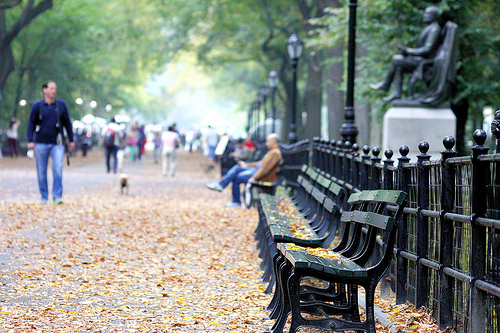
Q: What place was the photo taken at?
A: It was taken at the park.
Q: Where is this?
A: This is at the park.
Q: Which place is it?
A: It is a park.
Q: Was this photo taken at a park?
A: Yes, it was taken in a park.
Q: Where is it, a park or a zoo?
A: It is a park.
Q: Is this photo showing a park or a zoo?
A: It is showing a park.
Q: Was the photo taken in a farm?
A: No, the picture was taken in a park.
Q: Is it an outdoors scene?
A: Yes, it is outdoors.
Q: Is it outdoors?
A: Yes, it is outdoors.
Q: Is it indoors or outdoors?
A: It is outdoors.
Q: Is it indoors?
A: No, it is outdoors.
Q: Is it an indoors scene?
A: No, it is outdoors.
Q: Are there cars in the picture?
A: No, there are no cars.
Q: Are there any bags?
A: No, there are no bags.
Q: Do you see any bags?
A: No, there are no bags.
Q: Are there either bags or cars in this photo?
A: No, there are no bags or cars.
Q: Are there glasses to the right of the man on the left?
A: No, there are people to the right of the man.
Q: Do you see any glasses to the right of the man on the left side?
A: No, there are people to the right of the man.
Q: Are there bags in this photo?
A: No, there are no bags.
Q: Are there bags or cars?
A: No, there are no bags or cars.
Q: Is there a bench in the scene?
A: Yes, there is a bench.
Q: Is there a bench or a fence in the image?
A: Yes, there is a bench.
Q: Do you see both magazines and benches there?
A: No, there is a bench but no magazines.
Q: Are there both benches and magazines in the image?
A: No, there is a bench but no magazines.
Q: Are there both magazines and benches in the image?
A: No, there is a bench but no magazines.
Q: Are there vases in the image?
A: No, there are no vases.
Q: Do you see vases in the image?
A: No, there are no vases.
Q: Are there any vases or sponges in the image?
A: No, there are no vases or sponges.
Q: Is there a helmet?
A: No, there are no helmets.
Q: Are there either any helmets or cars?
A: No, there are no helmets or cars.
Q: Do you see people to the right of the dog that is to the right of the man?
A: Yes, there is a person to the right of the dog.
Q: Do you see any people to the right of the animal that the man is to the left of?
A: Yes, there is a person to the right of the dog.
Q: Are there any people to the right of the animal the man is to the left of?
A: Yes, there is a person to the right of the dog.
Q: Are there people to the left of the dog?
A: No, the person is to the right of the dog.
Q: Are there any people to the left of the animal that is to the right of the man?
A: No, the person is to the right of the dog.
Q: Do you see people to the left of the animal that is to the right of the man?
A: No, the person is to the right of the dog.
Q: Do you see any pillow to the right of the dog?
A: No, there is a person to the right of the dog.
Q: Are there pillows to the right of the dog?
A: No, there is a person to the right of the dog.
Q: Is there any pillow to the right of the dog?
A: No, there is a person to the right of the dog.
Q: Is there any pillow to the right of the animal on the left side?
A: No, there is a person to the right of the dog.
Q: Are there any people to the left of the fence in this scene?
A: Yes, there is a person to the left of the fence.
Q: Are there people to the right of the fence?
A: No, the person is to the left of the fence.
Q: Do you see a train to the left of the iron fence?
A: No, there is a person to the left of the fence.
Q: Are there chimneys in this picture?
A: No, there are no chimneys.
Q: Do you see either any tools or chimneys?
A: No, there are no chimneys or tools.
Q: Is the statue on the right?
A: Yes, the statue is on the right of the image.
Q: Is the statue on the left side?
A: No, the statue is on the right of the image.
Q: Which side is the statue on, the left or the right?
A: The statue is on the right of the image.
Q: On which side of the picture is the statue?
A: The statue is on the right of the image.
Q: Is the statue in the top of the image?
A: Yes, the statue is in the top of the image.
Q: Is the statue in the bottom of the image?
A: No, the statue is in the top of the image.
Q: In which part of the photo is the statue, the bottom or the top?
A: The statue is in the top of the image.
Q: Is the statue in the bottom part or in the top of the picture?
A: The statue is in the top of the image.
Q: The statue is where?
A: The statue is in the park.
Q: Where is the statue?
A: The statue is in the park.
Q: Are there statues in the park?
A: Yes, there is a statue in the park.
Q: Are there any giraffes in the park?
A: No, there is a statue in the park.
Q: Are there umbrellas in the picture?
A: No, there are no umbrellas.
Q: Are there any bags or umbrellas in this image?
A: No, there are no umbrellas or bags.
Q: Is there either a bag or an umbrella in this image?
A: No, there are no umbrellas or bags.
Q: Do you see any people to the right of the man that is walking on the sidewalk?
A: Yes, there are people to the right of the man.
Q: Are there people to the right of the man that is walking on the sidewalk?
A: Yes, there are people to the right of the man.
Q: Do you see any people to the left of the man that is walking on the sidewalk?
A: No, the people are to the right of the man.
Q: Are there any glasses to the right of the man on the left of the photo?
A: No, there are people to the right of the man.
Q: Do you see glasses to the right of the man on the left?
A: No, there are people to the right of the man.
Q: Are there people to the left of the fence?
A: Yes, there are people to the left of the fence.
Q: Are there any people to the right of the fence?
A: No, the people are to the left of the fence.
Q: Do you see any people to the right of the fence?
A: No, the people are to the left of the fence.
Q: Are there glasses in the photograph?
A: No, there are no glasses.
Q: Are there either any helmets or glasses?
A: No, there are no glasses or helmets.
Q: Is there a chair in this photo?
A: Yes, there is a chair.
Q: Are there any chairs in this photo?
A: Yes, there is a chair.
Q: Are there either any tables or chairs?
A: Yes, there is a chair.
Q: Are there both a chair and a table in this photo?
A: No, there is a chair but no tables.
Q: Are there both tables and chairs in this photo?
A: No, there is a chair but no tables.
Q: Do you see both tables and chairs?
A: No, there is a chair but no tables.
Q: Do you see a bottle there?
A: No, there are no bottles.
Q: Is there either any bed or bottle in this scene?
A: No, there are no bottles or beds.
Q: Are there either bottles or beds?
A: No, there are no bottles or beds.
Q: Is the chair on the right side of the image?
A: Yes, the chair is on the right of the image.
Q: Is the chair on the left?
A: No, the chair is on the right of the image.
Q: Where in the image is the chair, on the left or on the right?
A: The chair is on the right of the image.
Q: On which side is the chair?
A: The chair is on the right of the image.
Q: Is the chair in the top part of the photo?
A: Yes, the chair is in the top of the image.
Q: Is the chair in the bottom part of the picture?
A: No, the chair is in the top of the image.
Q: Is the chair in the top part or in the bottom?
A: The chair is in the top of the image.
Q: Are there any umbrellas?
A: No, there are no umbrellas.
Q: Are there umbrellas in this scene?
A: No, there are no umbrellas.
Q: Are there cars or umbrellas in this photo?
A: No, there are no umbrellas or cars.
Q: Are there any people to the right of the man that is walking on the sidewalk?
A: Yes, there are people to the right of the man.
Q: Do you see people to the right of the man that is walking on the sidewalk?
A: Yes, there are people to the right of the man.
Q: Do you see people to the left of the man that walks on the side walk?
A: No, the people are to the right of the man.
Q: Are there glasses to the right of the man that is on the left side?
A: No, there are people to the right of the man.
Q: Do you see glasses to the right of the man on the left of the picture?
A: No, there are people to the right of the man.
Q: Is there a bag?
A: No, there are no bags.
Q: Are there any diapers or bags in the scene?
A: No, there are no bags or diapers.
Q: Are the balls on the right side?
A: Yes, the balls are on the right of the image.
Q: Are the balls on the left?
A: No, the balls are on the right of the image.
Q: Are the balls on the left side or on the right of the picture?
A: The balls are on the right of the image.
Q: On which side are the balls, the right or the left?
A: The balls are on the right of the image.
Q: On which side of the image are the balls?
A: The balls are on the right of the image.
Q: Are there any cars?
A: No, there are no cars.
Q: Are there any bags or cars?
A: No, there are no cars or bags.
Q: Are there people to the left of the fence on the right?
A: Yes, there are people to the left of the fence.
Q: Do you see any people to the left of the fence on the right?
A: Yes, there are people to the left of the fence.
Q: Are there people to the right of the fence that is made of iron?
A: No, the people are to the left of the fence.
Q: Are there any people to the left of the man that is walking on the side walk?
A: No, the people are to the right of the man.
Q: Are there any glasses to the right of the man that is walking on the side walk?
A: No, there are people to the right of the man.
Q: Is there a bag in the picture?
A: No, there are no bags.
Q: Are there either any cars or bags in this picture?
A: No, there are no bags or cars.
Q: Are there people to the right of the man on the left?
A: Yes, there are people to the right of the man.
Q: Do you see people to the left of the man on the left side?
A: No, the people are to the right of the man.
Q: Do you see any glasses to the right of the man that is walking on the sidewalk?
A: No, there are people to the right of the man.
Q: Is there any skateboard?
A: No, there are no skateboards.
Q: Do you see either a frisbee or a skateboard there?
A: No, there are no skateboards or frisbees.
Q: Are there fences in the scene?
A: Yes, there is a fence.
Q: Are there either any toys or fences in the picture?
A: Yes, there is a fence.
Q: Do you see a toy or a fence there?
A: Yes, there is a fence.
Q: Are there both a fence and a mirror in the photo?
A: No, there is a fence but no mirrors.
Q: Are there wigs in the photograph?
A: No, there are no wigs.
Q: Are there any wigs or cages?
A: No, there are no wigs or cages.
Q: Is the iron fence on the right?
A: Yes, the fence is on the right of the image.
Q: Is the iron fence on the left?
A: No, the fence is on the right of the image.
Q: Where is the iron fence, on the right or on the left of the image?
A: The fence is on the right of the image.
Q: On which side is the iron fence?
A: The fence is on the right of the image.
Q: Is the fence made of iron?
A: Yes, the fence is made of iron.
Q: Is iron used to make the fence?
A: Yes, the fence is made of iron.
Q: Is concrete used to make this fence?
A: No, the fence is made of iron.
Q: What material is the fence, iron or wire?
A: The fence is made of iron.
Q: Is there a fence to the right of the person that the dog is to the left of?
A: Yes, there is a fence to the right of the person.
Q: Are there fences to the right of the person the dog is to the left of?
A: Yes, there is a fence to the right of the person.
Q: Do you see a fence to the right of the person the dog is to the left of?
A: Yes, there is a fence to the right of the person.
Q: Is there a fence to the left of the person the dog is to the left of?
A: No, the fence is to the right of the person.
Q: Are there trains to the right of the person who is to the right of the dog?
A: No, there is a fence to the right of the person.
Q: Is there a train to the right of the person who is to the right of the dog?
A: No, there is a fence to the right of the person.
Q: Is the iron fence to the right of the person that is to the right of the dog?
A: Yes, the fence is to the right of the person.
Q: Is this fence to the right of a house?
A: No, the fence is to the right of the person.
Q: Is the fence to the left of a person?
A: No, the fence is to the right of a person.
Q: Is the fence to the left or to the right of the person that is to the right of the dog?
A: The fence is to the right of the person.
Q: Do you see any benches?
A: Yes, there is a bench.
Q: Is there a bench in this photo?
A: Yes, there is a bench.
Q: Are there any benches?
A: Yes, there is a bench.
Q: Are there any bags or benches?
A: Yes, there is a bench.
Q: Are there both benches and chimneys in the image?
A: No, there is a bench but no chimneys.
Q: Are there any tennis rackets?
A: No, there are no tennis rackets.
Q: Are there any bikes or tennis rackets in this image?
A: No, there are no tennis rackets or bikes.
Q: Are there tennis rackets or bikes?
A: No, there are no tennis rackets or bikes.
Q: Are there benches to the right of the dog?
A: Yes, there is a bench to the right of the dog.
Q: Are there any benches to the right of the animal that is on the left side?
A: Yes, there is a bench to the right of the dog.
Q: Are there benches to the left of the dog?
A: No, the bench is to the right of the dog.